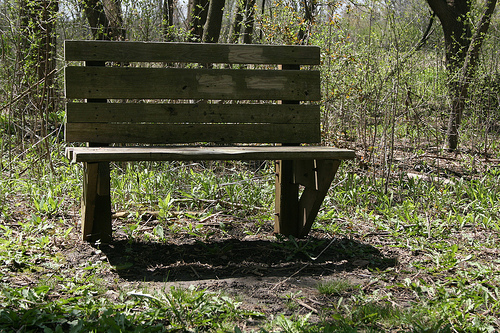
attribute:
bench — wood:
[58, 32, 357, 165]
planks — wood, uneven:
[51, 37, 331, 141]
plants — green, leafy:
[117, 164, 275, 243]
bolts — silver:
[270, 162, 282, 234]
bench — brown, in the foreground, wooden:
[46, 23, 356, 245]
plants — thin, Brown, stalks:
[335, 45, 422, 161]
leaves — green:
[314, 20, 425, 90]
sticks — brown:
[251, 210, 482, 279]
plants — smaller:
[362, 156, 462, 209]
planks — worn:
[57, 40, 322, 144]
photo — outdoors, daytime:
[2, 3, 476, 303]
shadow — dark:
[219, 232, 268, 269]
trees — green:
[154, 2, 449, 105]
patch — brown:
[165, 221, 259, 297]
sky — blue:
[96, 2, 346, 38]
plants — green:
[33, 250, 289, 329]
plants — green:
[313, 55, 439, 150]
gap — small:
[176, 36, 226, 97]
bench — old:
[157, 101, 284, 196]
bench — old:
[167, 60, 297, 170]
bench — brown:
[145, 58, 285, 171]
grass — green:
[47, 248, 148, 322]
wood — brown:
[120, 16, 280, 79]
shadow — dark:
[238, 96, 385, 288]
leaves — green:
[19, 46, 68, 157]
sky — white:
[75, 10, 137, 65]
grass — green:
[97, 273, 140, 323]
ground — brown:
[126, 256, 258, 330]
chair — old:
[94, 44, 319, 215]